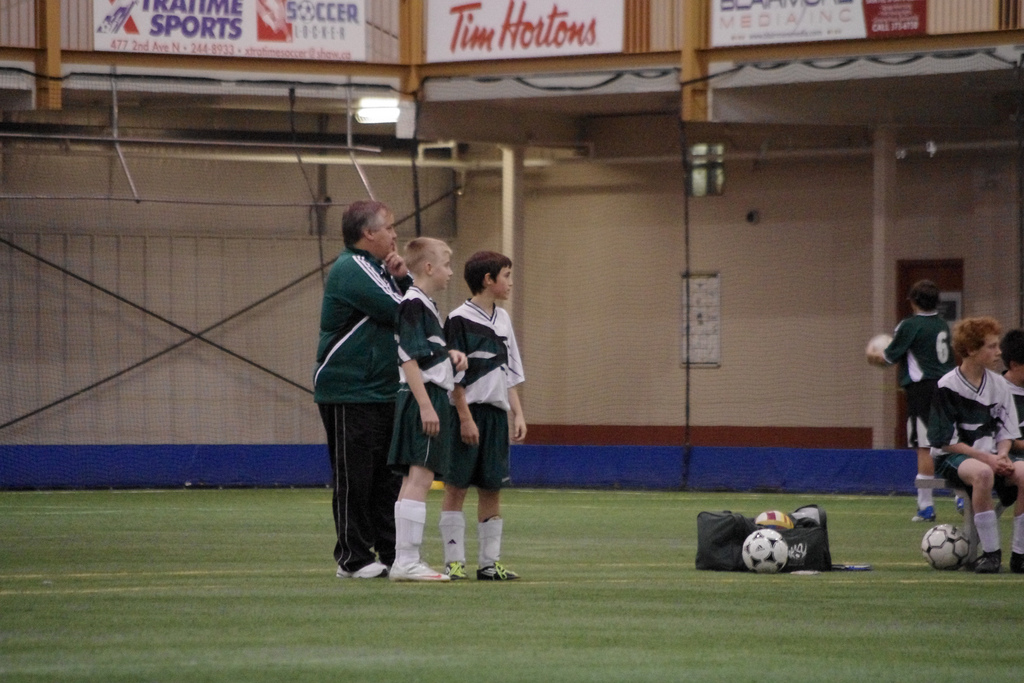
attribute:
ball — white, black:
[739, 525, 792, 575]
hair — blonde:
[391, 232, 450, 272]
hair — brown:
[464, 246, 516, 298]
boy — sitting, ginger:
[895, 310, 993, 514]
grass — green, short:
[6, 480, 992, 679]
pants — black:
[309, 394, 403, 576]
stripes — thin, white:
[324, 402, 351, 560]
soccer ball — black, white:
[734, 521, 804, 578]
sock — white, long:
[438, 506, 473, 569]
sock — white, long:
[471, 511, 504, 563]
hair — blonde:
[398, 232, 453, 267]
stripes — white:
[326, 398, 357, 567]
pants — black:
[317, 398, 400, 569]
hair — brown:
[456, 249, 502, 286]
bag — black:
[689, 504, 839, 572]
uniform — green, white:
[385, 282, 455, 490]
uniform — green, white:
[438, 292, 529, 496]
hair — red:
[930, 309, 1011, 405]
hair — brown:
[468, 242, 518, 305]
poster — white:
[675, 268, 740, 385]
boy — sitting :
[888, 312, 992, 570]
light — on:
[335, 80, 424, 132]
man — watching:
[337, 189, 437, 579]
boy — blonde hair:
[892, 292, 988, 543]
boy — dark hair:
[445, 229, 538, 582]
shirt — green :
[296, 256, 428, 393]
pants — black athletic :
[304, 379, 426, 596]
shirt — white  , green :
[335, 249, 511, 390]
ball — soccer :
[741, 530, 821, 583]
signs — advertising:
[105, 9, 963, 118]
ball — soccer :
[920, 491, 990, 571]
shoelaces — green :
[466, 545, 551, 576]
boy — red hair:
[913, 318, 991, 578]